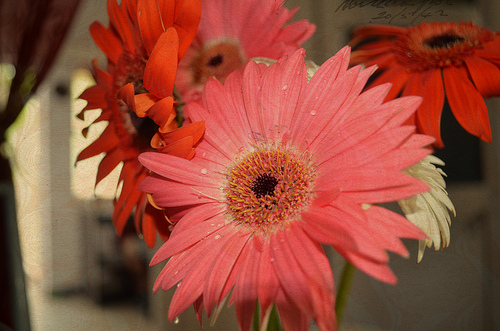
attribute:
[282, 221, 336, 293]
petal — pink 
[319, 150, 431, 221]
petal — pink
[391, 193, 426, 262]
petal — white 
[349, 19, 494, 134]
flower — red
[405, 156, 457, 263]
white petals — white  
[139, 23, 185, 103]
petals — red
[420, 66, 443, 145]
petal — red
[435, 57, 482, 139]
petal — red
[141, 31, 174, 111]
petal — red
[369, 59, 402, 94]
petal — red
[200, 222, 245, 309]
petal — red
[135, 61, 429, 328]
flower — pink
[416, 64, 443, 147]
petal — red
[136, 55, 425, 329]
petal — pink 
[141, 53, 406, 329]
flower — pink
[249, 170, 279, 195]
circle — small , dark 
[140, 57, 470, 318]
flower — white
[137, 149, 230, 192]
pink petal — pink 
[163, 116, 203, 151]
petals — orange , pink 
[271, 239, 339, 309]
petal — pink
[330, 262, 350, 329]
stem — green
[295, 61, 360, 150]
petal — pink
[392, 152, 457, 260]
flower — white, large, beautiful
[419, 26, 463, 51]
center — black, orange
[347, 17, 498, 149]
flower — orange 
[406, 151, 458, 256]
petals — white 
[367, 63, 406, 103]
petal — red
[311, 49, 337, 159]
petal — pink 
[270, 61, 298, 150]
petal — pink 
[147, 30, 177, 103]
petal — red